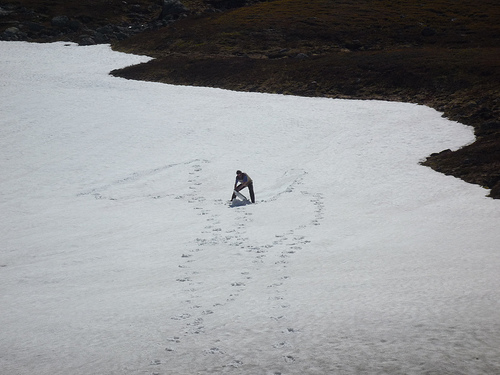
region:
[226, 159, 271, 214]
A man in snow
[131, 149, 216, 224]
snowy tracks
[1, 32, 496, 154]
the edge of the snow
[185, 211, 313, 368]
more tracks in the snow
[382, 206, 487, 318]
undisturbed snow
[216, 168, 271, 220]
a man standing from his sled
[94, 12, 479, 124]
the way the snow just ends is odd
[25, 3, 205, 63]
boulders in the distance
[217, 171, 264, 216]
a man playing in snow without proper warm weather attire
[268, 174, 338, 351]
more tracks in the snow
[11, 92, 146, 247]
snow on a mountain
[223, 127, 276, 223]
man coming down mountain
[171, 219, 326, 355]
footprints in the snow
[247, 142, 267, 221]
man's right leg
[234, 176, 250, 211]
man's left leg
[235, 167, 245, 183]
man's head covered in cap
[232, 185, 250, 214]
snow slide going downhill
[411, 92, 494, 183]
snow and water in the night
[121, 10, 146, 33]
two lights in the distance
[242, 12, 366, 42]
nighttime on the mountain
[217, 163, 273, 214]
person climbing through the snow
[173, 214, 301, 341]
footprints in the snow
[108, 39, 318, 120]
snow on the edge of the land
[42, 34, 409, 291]
person walking in the snow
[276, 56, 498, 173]
rocks at the edge of the snow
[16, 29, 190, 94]
wavy line between the dirt and the snow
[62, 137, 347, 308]
person making footprints in the snow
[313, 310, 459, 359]
dirty snow with footprints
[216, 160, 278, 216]
person during winter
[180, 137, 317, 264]
person trying to put on skis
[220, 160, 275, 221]
Person in the snow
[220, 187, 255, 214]
Thing the person is holding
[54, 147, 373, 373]
foot steps in the snow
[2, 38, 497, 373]
snow on the ground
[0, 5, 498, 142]
land without snow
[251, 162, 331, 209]
Trail right behind man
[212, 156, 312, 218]
man who has made the footsteps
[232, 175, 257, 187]
jacket man is wearing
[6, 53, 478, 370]
snow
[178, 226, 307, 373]
tracks in front of man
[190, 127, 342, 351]
the man in the field of snow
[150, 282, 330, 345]
snow prings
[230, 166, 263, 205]
a man with a snowboard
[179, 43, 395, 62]
a rocky field behind the snow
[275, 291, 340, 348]
snow tracks looking cool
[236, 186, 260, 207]
a white snowboard of the man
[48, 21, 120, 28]
rocky part of the world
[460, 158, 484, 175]
part of the rocks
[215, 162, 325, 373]
a cool shape made by tracks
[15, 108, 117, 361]
middle of no where